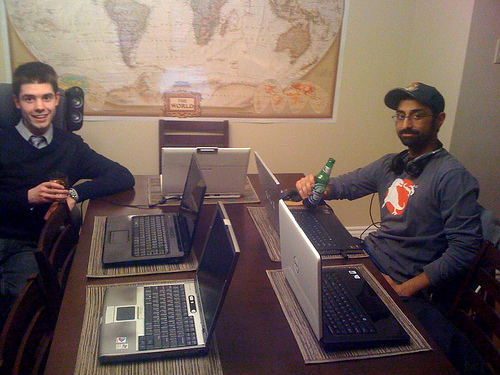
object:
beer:
[300, 156, 336, 210]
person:
[294, 82, 483, 298]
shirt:
[317, 150, 483, 287]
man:
[294, 80, 487, 299]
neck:
[406, 135, 439, 159]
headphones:
[387, 140, 443, 178]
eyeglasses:
[389, 110, 440, 124]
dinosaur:
[379, 177, 418, 217]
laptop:
[276, 197, 410, 349]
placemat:
[263, 260, 434, 367]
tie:
[27, 135, 47, 147]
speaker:
[70, 94, 84, 106]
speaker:
[68, 110, 83, 124]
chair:
[0, 80, 70, 135]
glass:
[48, 166, 70, 195]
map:
[2, 0, 351, 124]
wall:
[0, 0, 420, 242]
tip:
[157, 117, 230, 133]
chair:
[157, 119, 230, 176]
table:
[42, 171, 455, 374]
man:
[0, 61, 136, 305]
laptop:
[159, 145, 251, 200]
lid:
[160, 149, 252, 195]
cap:
[382, 81, 446, 110]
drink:
[52, 166, 68, 187]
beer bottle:
[300, 158, 337, 212]